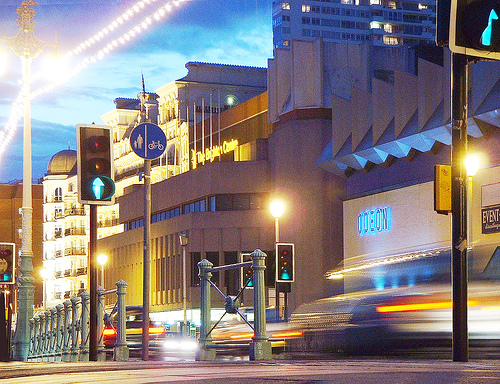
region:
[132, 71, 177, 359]
blue circular sign on metal pole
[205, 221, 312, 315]
traffic lights with green lights on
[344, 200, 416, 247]
blue neon sign lit up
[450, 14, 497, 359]
green light on pedestrian pole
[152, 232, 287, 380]
white barricade newar street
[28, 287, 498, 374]
many vehicles moving on street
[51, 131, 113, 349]
white building with dome top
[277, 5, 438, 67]
several rooms lit up on white building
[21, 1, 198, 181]
double string of lights up high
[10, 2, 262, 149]
dark blue sky with clouds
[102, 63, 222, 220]
a sign with a bike on it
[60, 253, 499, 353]
traffic in a blur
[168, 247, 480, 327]
this is a time lapse photo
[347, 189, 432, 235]
the word is odeon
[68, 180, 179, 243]
a green light is on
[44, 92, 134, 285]
red, yellow, green lights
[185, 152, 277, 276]
the building is brutalist style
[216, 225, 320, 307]
two traffic lights are green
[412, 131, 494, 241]
a walk button on a pole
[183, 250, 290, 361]
the fence is decorative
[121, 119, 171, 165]
The sign is blue.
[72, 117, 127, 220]
The light is green.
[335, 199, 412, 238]
The sign is teal.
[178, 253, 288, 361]
The poles are green.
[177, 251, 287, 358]
The poles are metal.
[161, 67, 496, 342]
The buildings are tall.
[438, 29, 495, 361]
The pole is metal.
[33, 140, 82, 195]
The roof is rounded.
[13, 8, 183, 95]
The lights are in the sky.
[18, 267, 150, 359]
The poles are manied.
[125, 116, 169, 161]
a blue sign on a pole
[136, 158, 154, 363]
a gray metal pole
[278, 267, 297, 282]
a green traffic light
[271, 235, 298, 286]
a bank of traffic lights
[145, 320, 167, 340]
a red tail light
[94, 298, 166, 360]
a black car on the road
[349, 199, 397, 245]
a blue sign on the building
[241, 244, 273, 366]
a short gray post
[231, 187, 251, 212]
the window on the building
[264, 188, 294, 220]
a yellow street ligh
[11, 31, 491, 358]
A city street scene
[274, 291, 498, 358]
The traffic is moving swiftly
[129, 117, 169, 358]
This is a street sign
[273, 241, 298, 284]
The traffic light is green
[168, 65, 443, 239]
Buildings are along the street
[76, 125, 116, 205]
The traffic signal shows a green arrow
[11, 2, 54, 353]
A lamp post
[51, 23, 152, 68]
strings of white lights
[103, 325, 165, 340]
A car's tail lights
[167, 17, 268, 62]
The sky is cloudy